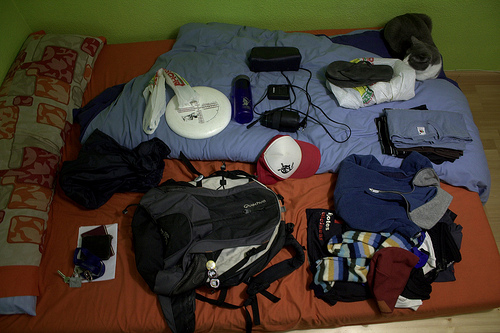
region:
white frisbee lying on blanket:
[173, 81, 235, 136]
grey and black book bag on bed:
[140, 195, 309, 284]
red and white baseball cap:
[244, 131, 333, 184]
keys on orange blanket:
[42, 259, 87, 306]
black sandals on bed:
[328, 51, 404, 101]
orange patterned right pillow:
[26, 42, 70, 142]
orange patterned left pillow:
[11, 157, 47, 257]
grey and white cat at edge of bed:
[384, 23, 444, 83]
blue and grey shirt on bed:
[341, 163, 438, 229]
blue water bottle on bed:
[226, 57, 254, 137]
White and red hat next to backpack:
[249, 130, 322, 200]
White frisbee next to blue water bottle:
[165, 85, 231, 137]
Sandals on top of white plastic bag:
[325, 52, 395, 87]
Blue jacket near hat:
[331, 148, 453, 242]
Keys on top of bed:
[52, 267, 90, 287]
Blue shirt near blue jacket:
[383, 104, 472, 151]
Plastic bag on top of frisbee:
[137, 65, 202, 135]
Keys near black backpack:
[57, 267, 97, 287]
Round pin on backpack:
[207, 275, 222, 289]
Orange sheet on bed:
[1, 23, 498, 330]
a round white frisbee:
[166, 83, 231, 140]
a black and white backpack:
[129, 173, 301, 306]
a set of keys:
[51, 262, 93, 287]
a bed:
[2, 30, 498, 329]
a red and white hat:
[250, 133, 320, 187]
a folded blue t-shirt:
[383, 107, 469, 149]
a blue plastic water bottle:
[227, 72, 254, 124]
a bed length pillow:
[3, 30, 100, 312]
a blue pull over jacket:
[330, 153, 449, 235]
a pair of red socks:
[366, 246, 416, 313]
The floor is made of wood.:
[283, 67, 498, 332]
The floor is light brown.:
[284, 68, 497, 331]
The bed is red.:
[0, 26, 499, 329]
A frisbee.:
[163, 80, 232, 140]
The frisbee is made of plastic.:
[164, 83, 231, 139]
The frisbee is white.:
[168, 83, 231, 141]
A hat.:
[253, 133, 320, 185]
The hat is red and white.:
[253, 133, 325, 185]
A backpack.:
[136, 168, 287, 288]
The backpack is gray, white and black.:
[133, 172, 287, 297]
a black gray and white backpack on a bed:
[117, 167, 302, 332]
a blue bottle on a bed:
[232, 73, 254, 121]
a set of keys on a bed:
[57, 245, 103, 290]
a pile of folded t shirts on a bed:
[372, 107, 472, 159]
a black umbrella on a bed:
[52, 129, 172, 207]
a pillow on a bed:
[0, 38, 100, 135]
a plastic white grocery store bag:
[137, 64, 194, 136]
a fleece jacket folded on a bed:
[332, 155, 444, 235]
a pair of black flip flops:
[326, 58, 393, 88]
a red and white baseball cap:
[255, 133, 320, 183]